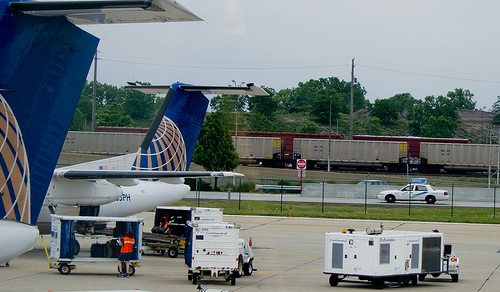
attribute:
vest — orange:
[116, 237, 135, 257]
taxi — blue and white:
[380, 178, 453, 205]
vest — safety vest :
[120, 235, 137, 254]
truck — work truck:
[186, 218, 254, 282]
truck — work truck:
[141, 206, 224, 257]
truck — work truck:
[323, 223, 460, 289]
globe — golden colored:
[138, 117, 186, 174]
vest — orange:
[118, 237, 135, 253]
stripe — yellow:
[121, 236, 135, 247]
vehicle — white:
[323, 228, 453, 278]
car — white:
[380, 177, 450, 206]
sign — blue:
[405, 177, 425, 187]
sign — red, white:
[295, 152, 309, 176]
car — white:
[373, 179, 451, 204]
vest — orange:
[118, 240, 142, 258]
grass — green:
[192, 195, 498, 225]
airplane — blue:
[32, 53, 269, 235]